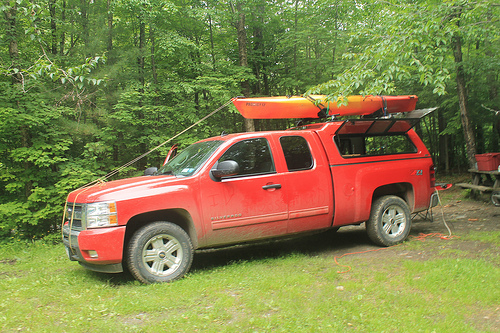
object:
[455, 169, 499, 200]
table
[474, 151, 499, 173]
bin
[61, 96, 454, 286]
truck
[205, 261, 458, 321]
grass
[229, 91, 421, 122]
canoe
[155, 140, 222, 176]
windshield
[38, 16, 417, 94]
woods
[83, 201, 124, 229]
headlight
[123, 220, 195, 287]
tire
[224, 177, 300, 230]
door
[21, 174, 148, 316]
front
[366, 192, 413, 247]
tire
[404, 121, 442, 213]
rear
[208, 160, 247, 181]
mirror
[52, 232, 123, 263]
fender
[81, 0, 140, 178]
tree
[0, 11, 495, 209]
background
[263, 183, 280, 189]
handle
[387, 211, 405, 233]
hubcap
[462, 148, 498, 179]
basket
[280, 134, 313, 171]
window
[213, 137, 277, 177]
window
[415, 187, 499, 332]
ground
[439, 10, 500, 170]
tree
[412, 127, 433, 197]
door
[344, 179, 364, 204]
tank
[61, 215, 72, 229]
logo